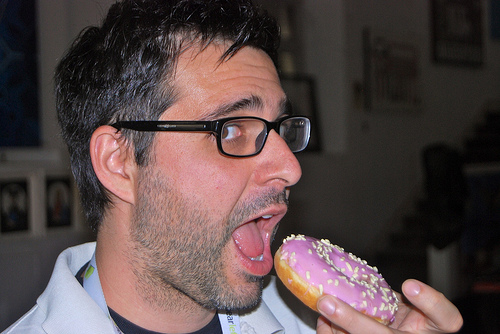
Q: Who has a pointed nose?
A: Man with glasses.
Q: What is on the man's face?
A: Glasses.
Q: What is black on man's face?
A: Glasses.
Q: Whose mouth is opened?
A: Man in glasses.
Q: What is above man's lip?
A: Mustache.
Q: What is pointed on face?
A: Nose.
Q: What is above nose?
A: Glasses.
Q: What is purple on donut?
A: Frosting.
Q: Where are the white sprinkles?
A: On top of donut.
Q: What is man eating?
A: Donut with frosting.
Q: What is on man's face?
A: Dark rimmed glasses.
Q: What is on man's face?
A: Scruffy beard.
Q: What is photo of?
A: Man about to eat donut.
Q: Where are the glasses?
A: On the man's face.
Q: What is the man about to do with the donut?
A: Eat it.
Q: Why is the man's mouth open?
A: To eat the doughnut.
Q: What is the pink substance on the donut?
A: Icing.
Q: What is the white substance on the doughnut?
A: Sprinkles.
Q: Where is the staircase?
A: Behind the man on the right.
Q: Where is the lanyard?
A: Around the man's neck.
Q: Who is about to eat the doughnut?
A: Man with glasses.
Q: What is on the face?
A: Beard.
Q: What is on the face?
A: Glasses.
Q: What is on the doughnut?
A: Sprinkles.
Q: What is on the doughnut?
A: Pink icing.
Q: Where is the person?
A: Home.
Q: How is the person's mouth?
A: Open.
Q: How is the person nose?
A: Pointed.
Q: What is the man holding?
A: Doughnut.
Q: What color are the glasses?
A: Black.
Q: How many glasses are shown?
A: One.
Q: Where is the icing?
A: On donut.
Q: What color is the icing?
A: Pink.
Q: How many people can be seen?
A: One.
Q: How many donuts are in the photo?
A: One.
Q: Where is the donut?
A: Man's hand.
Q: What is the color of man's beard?
A: Black.